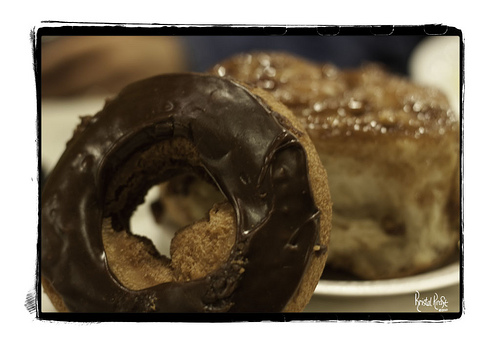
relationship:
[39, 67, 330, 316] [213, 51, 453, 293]
donut leaning on cinnamon roll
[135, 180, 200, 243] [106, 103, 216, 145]
hole in donut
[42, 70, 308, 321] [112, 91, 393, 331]
frosting on donut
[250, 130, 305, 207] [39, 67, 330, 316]
swirl on donut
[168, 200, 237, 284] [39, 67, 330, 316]
bulge in donut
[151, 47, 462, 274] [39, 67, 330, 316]
cinnamon bun behind donut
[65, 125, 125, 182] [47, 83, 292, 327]
light reflecting on donut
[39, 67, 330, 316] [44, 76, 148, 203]
donut sitting on table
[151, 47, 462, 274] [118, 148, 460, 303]
cinnamon bun on a plate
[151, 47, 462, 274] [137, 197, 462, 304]
cinnamon bun sitting on plate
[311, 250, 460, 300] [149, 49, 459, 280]
plate has pastry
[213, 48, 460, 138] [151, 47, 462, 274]
glaze on top of cinnamon bun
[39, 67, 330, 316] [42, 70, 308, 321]
donut with frosting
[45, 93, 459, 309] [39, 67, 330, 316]
table with donut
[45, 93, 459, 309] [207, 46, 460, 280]
table with donut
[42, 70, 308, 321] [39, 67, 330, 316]
frosting on donut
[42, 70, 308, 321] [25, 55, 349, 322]
frosting on donut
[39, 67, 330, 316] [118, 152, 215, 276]
donut has hole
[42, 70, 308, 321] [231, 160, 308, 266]
frosting on donut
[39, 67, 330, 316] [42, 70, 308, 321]
donut has frosting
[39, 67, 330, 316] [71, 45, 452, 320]
donut on plate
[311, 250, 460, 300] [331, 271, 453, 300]
plate has edge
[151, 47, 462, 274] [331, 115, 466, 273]
cinnamon bun has edge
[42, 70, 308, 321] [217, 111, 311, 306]
frosting has bumps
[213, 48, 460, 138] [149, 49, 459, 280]
glaze glistening off pastry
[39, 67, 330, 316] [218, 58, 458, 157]
donut with glaze